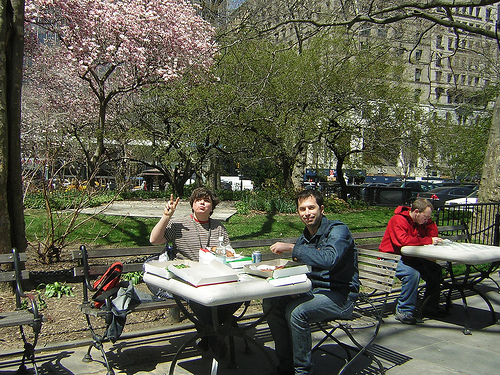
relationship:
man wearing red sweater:
[379, 182, 434, 310] [385, 207, 436, 249]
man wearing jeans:
[270, 186, 362, 373] [281, 285, 356, 373]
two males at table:
[140, 119, 341, 276] [131, 231, 324, 322]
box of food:
[238, 232, 301, 302] [235, 244, 322, 289]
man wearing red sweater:
[379, 199, 445, 324] [376, 206, 438, 262]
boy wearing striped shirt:
[147, 182, 237, 360] [160, 213, 235, 260]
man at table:
[379, 199, 445, 324] [405, 221, 495, 319]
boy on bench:
[149, 188, 237, 359] [70, 240, 400, 374]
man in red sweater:
[379, 199, 445, 324] [376, 206, 438, 262]